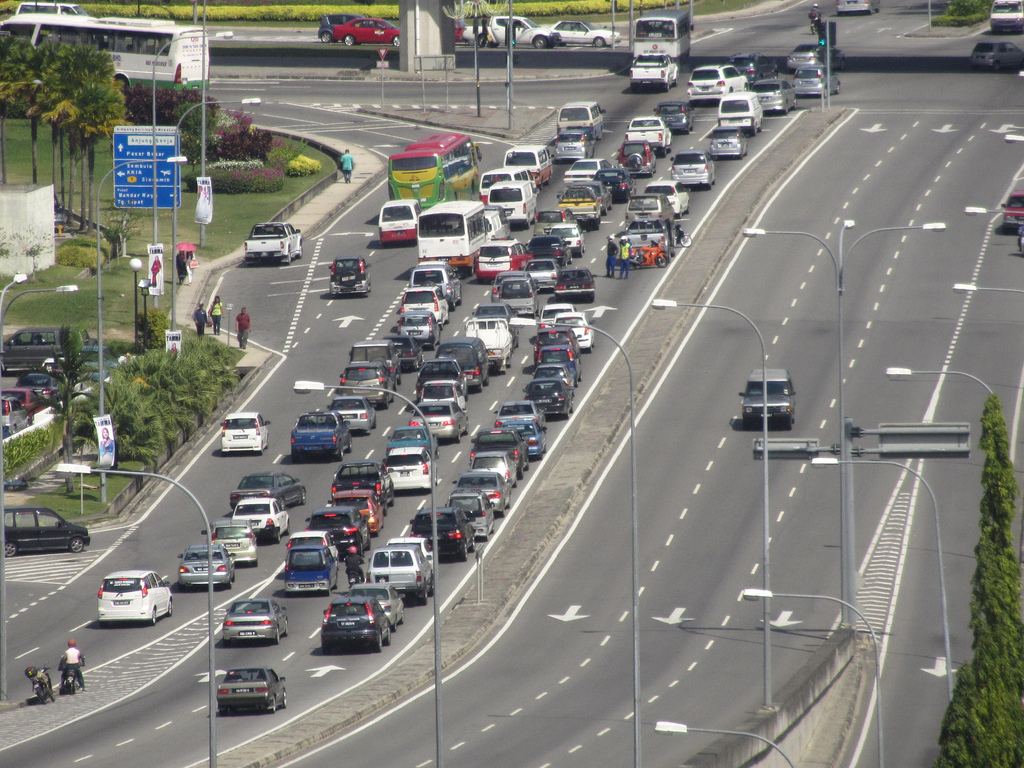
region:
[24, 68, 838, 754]
THE TRAFFIC IS ALL ON ONE SIDE OF THE ROAD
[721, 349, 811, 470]
THE VAN IS GREY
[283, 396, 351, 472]
THE TRUCK IS BLUE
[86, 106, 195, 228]
THE SIGN IS BLUE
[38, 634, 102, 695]
THE MAN IS ON THE BIKE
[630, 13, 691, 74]
THE BUS IS UNDER THE BRIDGE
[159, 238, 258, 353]
THE PEOPLE ARE ON THE SIDEWALK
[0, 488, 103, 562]
THE VAN IS BLACK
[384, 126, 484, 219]
Red yellow and green bus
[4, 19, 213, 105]
Very big white bus with green on bottom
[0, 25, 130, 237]
Palm trees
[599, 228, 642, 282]
Men diverting traffic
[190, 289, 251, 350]
Three people near each other on sidewalk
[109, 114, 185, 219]
Blue traffic sign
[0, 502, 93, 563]
Crappy black minivan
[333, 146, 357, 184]
Guy in sea foam green tshirt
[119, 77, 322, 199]
Nicely manicured display of flowers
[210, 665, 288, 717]
a car on a street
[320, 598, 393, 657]
a car on a street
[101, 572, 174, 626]
a car on a street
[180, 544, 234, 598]
a car on a street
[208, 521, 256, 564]
a car on a street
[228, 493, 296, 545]
a car on a street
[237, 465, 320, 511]
a car on a street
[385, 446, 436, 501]
a car on a street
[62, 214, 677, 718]
many cars on the street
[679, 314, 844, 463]
one car on the street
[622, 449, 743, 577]
white lines on the ground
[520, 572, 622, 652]
white arrow on street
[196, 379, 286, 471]
white car on the street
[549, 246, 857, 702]
pole next to street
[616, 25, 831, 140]
cars in the distance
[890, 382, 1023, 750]
tree next to the street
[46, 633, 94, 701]
a man on a motorcycle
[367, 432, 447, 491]
this car is white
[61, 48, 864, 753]
these are cars in traffic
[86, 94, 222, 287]
a large blue sign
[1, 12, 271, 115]
this bus is white and green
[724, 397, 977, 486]
the back of a road sign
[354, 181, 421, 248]
this is a white and red van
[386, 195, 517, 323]
cars stuck in traffic jam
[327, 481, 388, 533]
cars stuck in traffic jam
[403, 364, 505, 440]
cars stuck in traffic jam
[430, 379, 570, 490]
cars stuck in traffic jam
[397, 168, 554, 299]
cars stuck in traffic jam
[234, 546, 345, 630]
cars stuck in traffic jam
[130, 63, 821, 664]
cars on the street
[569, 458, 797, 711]
white lines on ground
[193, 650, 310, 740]
small car on highway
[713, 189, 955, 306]
top of the pole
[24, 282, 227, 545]
trees next to the highway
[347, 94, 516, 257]
bus on the street